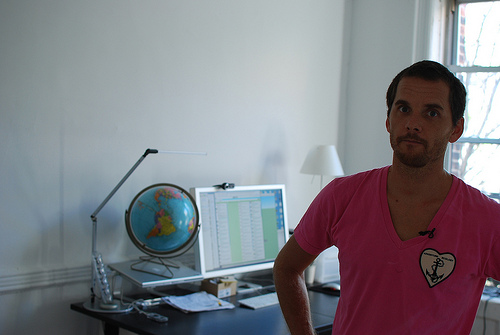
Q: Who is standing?
A: A man.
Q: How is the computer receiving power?
A: Through a electric cable.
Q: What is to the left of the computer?
A: A globe.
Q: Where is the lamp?
A: The back right corner of the room.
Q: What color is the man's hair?
A: Black.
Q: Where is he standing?
A: In a room.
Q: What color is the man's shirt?
A: Pink.